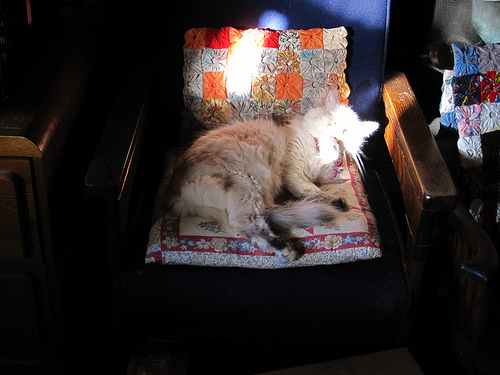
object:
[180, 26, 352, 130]
seat cover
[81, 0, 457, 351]
seat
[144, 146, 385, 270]
seat cover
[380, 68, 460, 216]
seat handle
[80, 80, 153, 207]
seat handle